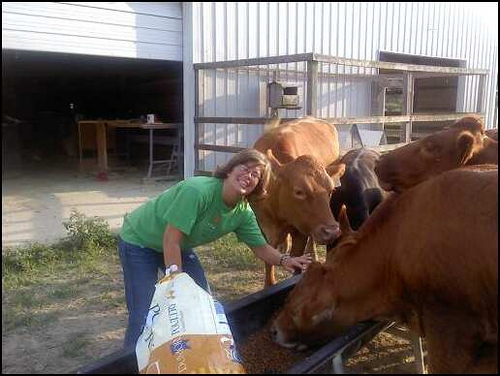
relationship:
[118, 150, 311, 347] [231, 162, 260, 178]
lady has glasses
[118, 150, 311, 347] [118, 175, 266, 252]
lady has shirt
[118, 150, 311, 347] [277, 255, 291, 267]
lady has bracelet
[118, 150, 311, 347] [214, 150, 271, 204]
lady has hair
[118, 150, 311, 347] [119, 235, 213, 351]
lady has jeans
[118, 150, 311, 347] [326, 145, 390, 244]
lady feeding cow